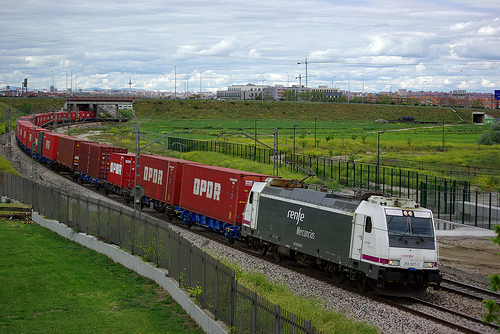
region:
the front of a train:
[316, 172, 470, 292]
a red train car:
[111, 132, 288, 236]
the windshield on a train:
[344, 198, 449, 273]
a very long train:
[40, 39, 410, 237]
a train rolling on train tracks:
[289, 131, 454, 299]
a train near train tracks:
[148, 126, 350, 293]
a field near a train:
[239, 66, 376, 171]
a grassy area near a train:
[34, 248, 119, 312]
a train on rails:
[8, 98, 498, 323]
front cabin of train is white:
[350, 194, 447, 291]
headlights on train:
[381, 250, 438, 270]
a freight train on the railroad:
[11, 105, 446, 289]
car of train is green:
[253, 175, 357, 275]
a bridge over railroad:
[54, 90, 135, 122]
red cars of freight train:
[8, 98, 252, 229]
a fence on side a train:
[2, 165, 313, 332]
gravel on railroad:
[299, 280, 487, 332]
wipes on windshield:
[382, 203, 437, 253]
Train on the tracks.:
[17, 108, 453, 305]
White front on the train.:
[343, 183, 443, 277]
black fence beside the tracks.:
[162, 130, 495, 227]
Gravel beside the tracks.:
[1, 132, 487, 332]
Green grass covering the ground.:
[0, 211, 201, 332]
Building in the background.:
[209, 82, 313, 101]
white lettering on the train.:
[185, 172, 226, 201]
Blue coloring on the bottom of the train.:
[174, 199, 238, 238]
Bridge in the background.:
[60, 90, 149, 136]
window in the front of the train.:
[382, 209, 439, 254]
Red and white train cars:
[17, 85, 254, 252]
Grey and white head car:
[240, 158, 449, 285]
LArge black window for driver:
[368, 203, 439, 259]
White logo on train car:
[190, 172, 225, 207]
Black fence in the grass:
[159, 131, 498, 253]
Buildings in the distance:
[219, 77, 499, 114]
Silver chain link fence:
[2, 167, 333, 332]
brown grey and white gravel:
[9, 128, 498, 332]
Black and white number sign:
[397, 203, 420, 221]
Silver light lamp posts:
[294, 51, 317, 99]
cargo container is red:
[20, 108, 252, 242]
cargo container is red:
[77, 133, 207, 218]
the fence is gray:
[52, 180, 264, 330]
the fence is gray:
[32, 177, 189, 285]